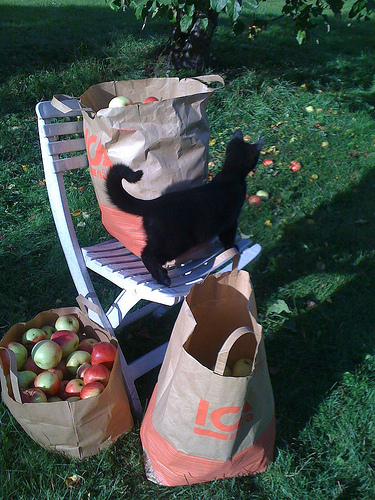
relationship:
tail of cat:
[105, 165, 152, 217] [105, 130, 261, 282]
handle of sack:
[73, 297, 121, 315] [0, 297, 132, 462]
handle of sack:
[1, 367, 19, 403] [0, 297, 132, 462]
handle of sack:
[208, 246, 240, 272] [136, 247, 278, 487]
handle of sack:
[212, 326, 266, 377] [136, 247, 278, 487]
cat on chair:
[105, 130, 261, 282] [37, 96, 263, 421]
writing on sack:
[191, 397, 256, 442] [136, 247, 278, 487]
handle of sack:
[50, 92, 80, 117] [50, 71, 226, 271]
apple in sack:
[90, 341, 112, 369] [0, 297, 132, 462]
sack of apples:
[50, 71, 226, 271] [94, 93, 179, 121]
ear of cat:
[253, 137, 264, 150] [105, 130, 261, 282]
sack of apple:
[0, 297, 132, 462] [90, 341, 112, 369]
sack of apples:
[136, 247, 278, 487] [208, 353, 252, 379]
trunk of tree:
[157, 48, 223, 73] [106, 1, 373, 81]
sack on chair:
[50, 71, 226, 271] [37, 96, 263, 421]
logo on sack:
[80, 134, 110, 178] [50, 71, 226, 271]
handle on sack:
[193, 72, 230, 98] [50, 71, 226, 271]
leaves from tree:
[264, 150, 304, 208] [106, 1, 373, 81]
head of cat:
[220, 132, 263, 176] [105, 130, 261, 282]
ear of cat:
[232, 126, 244, 142] [105, 130, 261, 282]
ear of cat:
[253, 140, 260, 152] [105, 130, 261, 282]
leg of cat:
[142, 246, 170, 287] [105, 130, 261, 282]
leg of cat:
[226, 228, 240, 256] [105, 130, 261, 282]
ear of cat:
[227, 126, 244, 142] [105, 130, 261, 282]